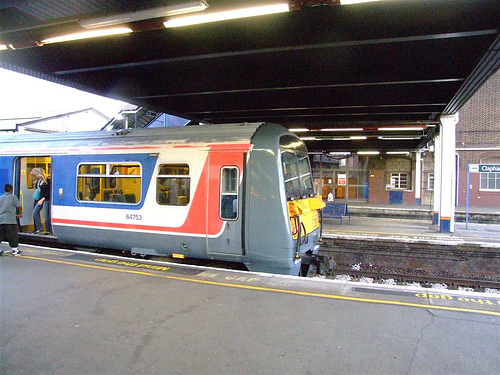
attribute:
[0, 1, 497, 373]
station — large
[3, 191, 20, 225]
shirt — gray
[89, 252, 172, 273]
lettering — yellow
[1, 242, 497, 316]
stripe — yellow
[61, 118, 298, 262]
paint — white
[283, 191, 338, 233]
bumper — yellow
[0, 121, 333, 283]
train — red, blue, white, large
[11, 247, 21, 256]
sneaker — white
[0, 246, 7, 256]
sneaker — white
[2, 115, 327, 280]
paint — gray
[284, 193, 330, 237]
paint — yellow